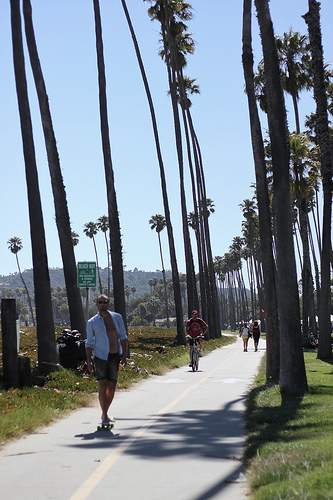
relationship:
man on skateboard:
[87, 294, 126, 421] [98, 421, 114, 430]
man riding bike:
[186, 309, 207, 368] [186, 335, 203, 371]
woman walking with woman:
[240, 322, 250, 352] [253, 322, 260, 352]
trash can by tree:
[56, 326, 86, 370] [11, 29, 58, 378]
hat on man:
[191, 309, 196, 314] [186, 309, 207, 368]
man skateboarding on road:
[87, 294, 126, 421] [11, 346, 265, 497]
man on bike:
[186, 309, 207, 368] [186, 335, 203, 371]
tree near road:
[11, 29, 58, 378] [11, 346, 265, 497]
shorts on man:
[92, 352, 120, 381] [87, 294, 126, 421]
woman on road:
[253, 322, 260, 352] [11, 346, 265, 497]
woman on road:
[240, 322, 250, 352] [11, 346, 265, 497]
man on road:
[87, 294, 126, 421] [11, 346, 265, 497]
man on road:
[186, 309, 207, 368] [11, 346, 265, 497]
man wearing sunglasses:
[87, 294, 126, 421] [97, 300, 110, 305]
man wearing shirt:
[87, 294, 126, 421] [86, 311, 128, 361]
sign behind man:
[77, 261, 95, 287] [87, 294, 126, 421]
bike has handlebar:
[186, 335, 203, 371] [184, 335, 194, 339]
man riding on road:
[186, 309, 207, 368] [11, 346, 265, 497]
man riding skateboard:
[87, 294, 126, 421] [98, 421, 114, 430]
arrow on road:
[212, 377, 248, 385] [11, 346, 265, 497]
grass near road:
[244, 348, 331, 499] [11, 346, 265, 497]